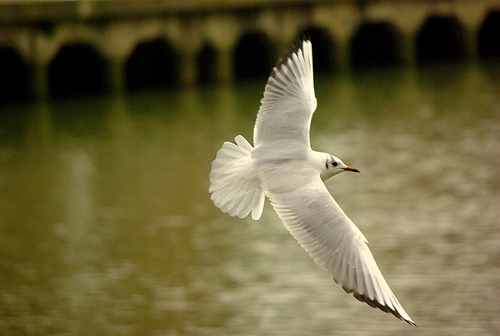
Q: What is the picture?
A: Bird.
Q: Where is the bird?
A: Air.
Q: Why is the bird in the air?
A: To fly.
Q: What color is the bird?
A: White.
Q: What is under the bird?
A: Water.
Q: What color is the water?
A: Brown.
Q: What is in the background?
A: Bridge.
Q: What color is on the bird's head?
A: Black.